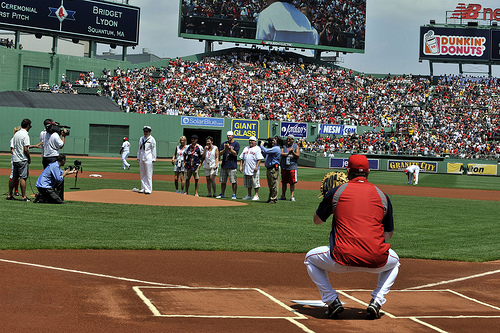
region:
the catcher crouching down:
[303, 153, 400, 318]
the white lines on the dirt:
[0, 255, 498, 332]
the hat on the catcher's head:
[346, 153, 370, 169]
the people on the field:
[6, 120, 419, 312]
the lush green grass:
[0, 155, 499, 263]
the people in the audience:
[36, 49, 499, 160]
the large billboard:
[418, 28, 498, 65]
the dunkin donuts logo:
[423, 29, 485, 57]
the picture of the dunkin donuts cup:
[425, 28, 440, 53]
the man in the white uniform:
[138, 125, 158, 192]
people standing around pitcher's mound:
[24, 101, 351, 247]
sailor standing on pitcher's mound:
[37, 113, 262, 223]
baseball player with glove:
[253, 118, 434, 330]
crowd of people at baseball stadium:
[162, 46, 462, 290]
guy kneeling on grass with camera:
[27, 152, 107, 222]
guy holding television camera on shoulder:
[22, 102, 93, 189]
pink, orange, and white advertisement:
[439, 16, 499, 75]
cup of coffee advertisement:
[410, 19, 447, 61]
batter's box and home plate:
[97, 205, 484, 331]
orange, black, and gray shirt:
[314, 147, 416, 278]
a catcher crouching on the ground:
[296, 147, 402, 321]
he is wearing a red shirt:
[323, 179, 393, 266]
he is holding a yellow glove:
[315, 167, 349, 199]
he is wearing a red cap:
[344, 154, 367, 169]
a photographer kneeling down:
[23, 154, 76, 205]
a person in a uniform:
[131, 122, 160, 197]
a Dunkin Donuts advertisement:
[417, 25, 492, 62]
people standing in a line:
[167, 127, 305, 202]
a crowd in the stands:
[48, 52, 498, 169]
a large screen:
[172, 1, 369, 58]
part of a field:
[169, 235, 188, 259]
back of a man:
[356, 204, 363, 236]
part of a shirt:
[331, 193, 341, 239]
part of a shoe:
[338, 311, 345, 317]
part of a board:
[436, 158, 447, 163]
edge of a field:
[210, 212, 225, 242]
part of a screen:
[230, 10, 236, 22]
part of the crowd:
[168, 58, 178, 81]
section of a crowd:
[111, 90, 114, 113]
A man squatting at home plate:
[301, 151, 401, 318]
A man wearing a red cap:
[343, 151, 371, 181]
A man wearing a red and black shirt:
[313, 176, 397, 268]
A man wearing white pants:
[302, 240, 398, 301]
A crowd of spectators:
[400, 78, 497, 153]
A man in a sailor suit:
[136, 123, 158, 196]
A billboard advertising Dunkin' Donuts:
[417, 22, 496, 72]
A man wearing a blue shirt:
[34, 153, 73, 190]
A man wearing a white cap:
[223, 128, 235, 143]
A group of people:
[171, 132, 301, 204]